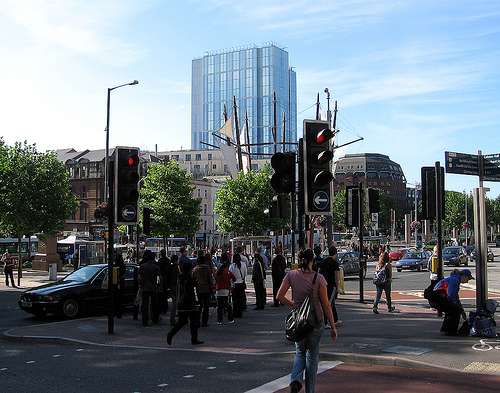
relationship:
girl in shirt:
[272, 247, 339, 386] [280, 268, 326, 321]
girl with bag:
[272, 247, 339, 386] [283, 270, 323, 345]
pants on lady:
[427, 293, 463, 328] [424, 266, 479, 338]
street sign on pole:
[434, 145, 499, 181] [472, 174, 490, 310]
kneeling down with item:
[425, 267, 476, 338] [471, 296, 493, 351]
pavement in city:
[0, 281, 500, 392] [0, 44, 499, 285]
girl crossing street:
[272, 247, 340, 393] [39, 299, 353, 390]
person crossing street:
[368, 246, 400, 313] [39, 299, 353, 390]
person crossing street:
[161, 255, 209, 347] [39, 299, 353, 390]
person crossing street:
[215, 246, 242, 324] [39, 299, 353, 390]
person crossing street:
[224, 247, 251, 324] [39, 299, 353, 390]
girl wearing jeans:
[272, 247, 340, 393] [279, 320, 341, 388]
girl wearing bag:
[272, 247, 340, 393] [277, 261, 324, 343]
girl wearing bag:
[272, 247, 340, 393] [282, 292, 329, 339]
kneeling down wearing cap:
[425, 267, 476, 338] [463, 268, 479, 285]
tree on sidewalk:
[2, 136, 76, 263] [2, 265, 59, 281]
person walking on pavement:
[372, 251, 397, 315] [0, 281, 500, 392]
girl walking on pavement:
[272, 247, 340, 393] [0, 281, 500, 392]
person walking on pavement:
[213, 259, 237, 325] [0, 281, 500, 392]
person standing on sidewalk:
[0, 252, 21, 291] [0, 256, 80, 283]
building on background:
[191, 43, 305, 156] [101, 82, 364, 132]